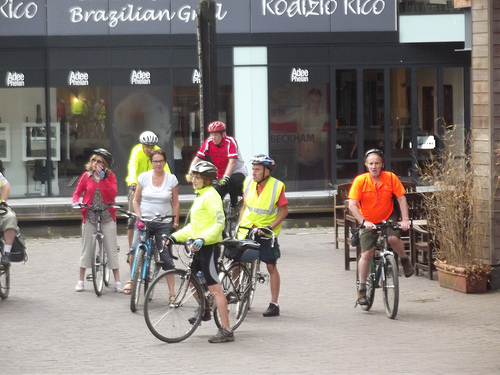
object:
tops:
[168, 184, 226, 246]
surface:
[0, 327, 499, 374]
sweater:
[69, 168, 117, 223]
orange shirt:
[348, 170, 406, 223]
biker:
[186, 120, 250, 219]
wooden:
[327, 166, 442, 279]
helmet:
[207, 121, 227, 138]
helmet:
[249, 153, 278, 173]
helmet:
[138, 130, 158, 146]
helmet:
[93, 147, 115, 167]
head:
[250, 153, 276, 183]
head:
[208, 121, 227, 144]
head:
[189, 160, 220, 189]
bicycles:
[0, 208, 11, 300]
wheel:
[378, 252, 401, 319]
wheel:
[142, 267, 205, 343]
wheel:
[126, 247, 146, 315]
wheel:
[90, 235, 103, 297]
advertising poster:
[268, 66, 332, 189]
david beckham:
[268, 87, 331, 192]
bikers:
[0, 172, 20, 266]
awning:
[0, 0, 398, 48]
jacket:
[124, 142, 170, 185]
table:
[342, 187, 439, 265]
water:
[20, 211, 421, 233]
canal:
[5, 204, 334, 241]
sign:
[1, 0, 401, 37]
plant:
[403, 108, 500, 284]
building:
[0, 0, 500, 293]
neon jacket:
[232, 172, 286, 242]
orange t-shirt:
[255, 180, 289, 209]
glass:
[447, 67, 467, 162]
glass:
[417, 63, 437, 173]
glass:
[389, 66, 414, 151]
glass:
[365, 68, 388, 155]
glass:
[338, 66, 360, 177]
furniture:
[334, 67, 389, 189]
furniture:
[416, 69, 467, 179]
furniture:
[172, 83, 234, 174]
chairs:
[333, 183, 413, 279]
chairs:
[410, 217, 435, 281]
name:
[288, 65, 316, 87]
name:
[127, 70, 154, 85]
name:
[3, 69, 28, 88]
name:
[67, 68, 90, 87]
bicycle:
[356, 217, 406, 317]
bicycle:
[144, 237, 253, 343]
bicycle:
[74, 204, 115, 296]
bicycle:
[122, 211, 174, 311]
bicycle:
[226, 225, 276, 319]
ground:
[1, 227, 500, 375]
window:
[0, 46, 229, 197]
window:
[269, 42, 469, 193]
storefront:
[3, 2, 470, 219]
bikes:
[126, 130, 172, 270]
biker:
[348, 149, 409, 305]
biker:
[232, 153, 289, 318]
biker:
[169, 160, 236, 344]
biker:
[120, 150, 180, 305]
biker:
[71, 147, 124, 295]